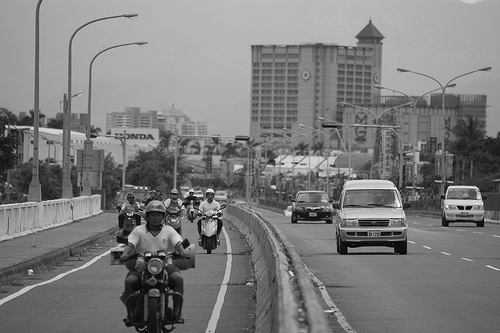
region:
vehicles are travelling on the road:
[231, 133, 498, 316]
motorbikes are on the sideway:
[101, 160, 238, 332]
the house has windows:
[237, 20, 409, 165]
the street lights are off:
[30, 2, 174, 194]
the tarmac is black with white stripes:
[306, 240, 499, 330]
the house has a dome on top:
[282, 0, 400, 92]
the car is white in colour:
[328, 161, 405, 259]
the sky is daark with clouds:
[158, 20, 220, 93]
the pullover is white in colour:
[126, 222, 190, 327]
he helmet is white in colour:
[186, 180, 218, 197]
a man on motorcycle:
[106, 194, 196, 330]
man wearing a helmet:
[139, 194, 169, 221]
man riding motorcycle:
[114, 243, 191, 331]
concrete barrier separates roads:
[219, 195, 334, 331]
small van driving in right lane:
[332, 169, 414, 256]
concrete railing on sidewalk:
[1, 190, 115, 247]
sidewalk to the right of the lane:
[1, 200, 125, 286]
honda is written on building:
[112, 127, 157, 144]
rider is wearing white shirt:
[121, 220, 184, 267]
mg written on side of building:
[347, 105, 374, 145]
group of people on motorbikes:
[112, 187, 228, 332]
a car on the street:
[332, 178, 409, 259]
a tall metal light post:
[60, 13, 137, 198]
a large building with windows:
[247, 18, 382, 144]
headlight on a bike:
[145, 257, 163, 274]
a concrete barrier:
[220, 201, 326, 331]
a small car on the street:
[289, 186, 333, 226]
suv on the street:
[439, 181, 486, 228]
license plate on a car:
[365, 230, 382, 239]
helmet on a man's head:
[142, 199, 166, 214]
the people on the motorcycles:
[108, 186, 227, 331]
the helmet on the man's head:
[142, 199, 164, 212]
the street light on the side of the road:
[60, 13, 137, 198]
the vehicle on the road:
[331, 179, 407, 254]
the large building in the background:
[250, 17, 385, 153]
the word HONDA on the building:
[115, 132, 154, 141]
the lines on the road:
[0, 223, 232, 331]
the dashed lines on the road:
[403, 212, 498, 272]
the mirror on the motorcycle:
[182, 236, 191, 250]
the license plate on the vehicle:
[366, 229, 381, 237]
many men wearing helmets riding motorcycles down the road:
[108, 177, 238, 331]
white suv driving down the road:
[331, 172, 416, 256]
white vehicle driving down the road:
[438, 182, 488, 227]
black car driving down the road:
[284, 187, 335, 226]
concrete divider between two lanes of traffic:
[234, 216, 311, 329]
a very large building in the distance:
[243, 12, 389, 158]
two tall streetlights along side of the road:
[60, 7, 157, 106]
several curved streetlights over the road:
[368, 66, 498, 111]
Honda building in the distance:
[111, 125, 159, 149]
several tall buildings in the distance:
[99, 101, 218, 137]